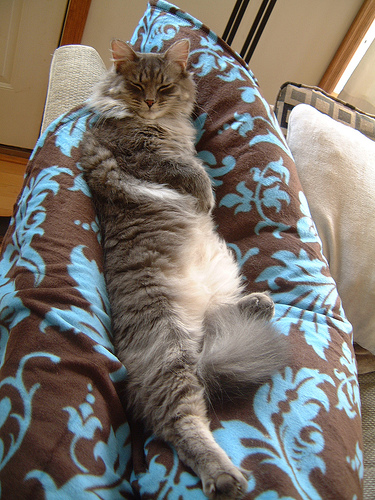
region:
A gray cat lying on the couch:
[68, 38, 264, 492]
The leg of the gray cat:
[152, 413, 243, 467]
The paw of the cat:
[197, 458, 257, 499]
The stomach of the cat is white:
[141, 188, 246, 318]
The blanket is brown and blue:
[224, 95, 348, 491]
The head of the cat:
[109, 34, 199, 124]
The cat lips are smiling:
[127, 104, 174, 118]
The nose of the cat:
[140, 96, 158, 109]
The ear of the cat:
[159, 35, 192, 75]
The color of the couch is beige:
[40, 35, 106, 152]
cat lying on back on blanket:
[83, 28, 277, 497]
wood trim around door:
[59, 4, 86, 54]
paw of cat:
[197, 465, 261, 495]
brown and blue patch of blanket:
[6, 306, 131, 495]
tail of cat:
[185, 300, 288, 420]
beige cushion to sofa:
[285, 103, 373, 295]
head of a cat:
[102, 29, 194, 120]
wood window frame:
[311, 3, 364, 99]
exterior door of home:
[2, 17, 48, 153]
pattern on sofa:
[276, 69, 369, 133]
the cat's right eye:
[129, 75, 146, 92]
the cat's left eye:
[156, 76, 173, 92]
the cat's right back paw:
[193, 445, 254, 498]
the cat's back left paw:
[228, 285, 277, 321]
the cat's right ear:
[109, 34, 141, 68]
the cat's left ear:
[160, 30, 195, 68]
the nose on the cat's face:
[143, 95, 156, 105]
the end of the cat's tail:
[201, 303, 286, 395]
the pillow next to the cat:
[277, 79, 373, 359]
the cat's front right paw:
[190, 162, 221, 216]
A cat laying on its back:
[87, 29, 270, 495]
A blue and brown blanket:
[16, 130, 125, 496]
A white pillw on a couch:
[292, 112, 371, 309]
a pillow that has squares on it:
[279, 75, 359, 123]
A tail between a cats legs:
[208, 309, 285, 394]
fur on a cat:
[101, 177, 199, 339]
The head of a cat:
[101, 30, 199, 132]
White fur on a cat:
[186, 235, 238, 323]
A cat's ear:
[160, 33, 207, 69]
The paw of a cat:
[177, 447, 264, 498]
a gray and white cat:
[64, 28, 304, 498]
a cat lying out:
[73, 29, 314, 498]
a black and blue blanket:
[5, 2, 371, 498]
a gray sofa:
[28, 37, 114, 164]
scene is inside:
[4, 3, 374, 498]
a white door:
[0, 0, 75, 169]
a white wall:
[83, 1, 350, 117]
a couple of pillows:
[260, 59, 373, 347]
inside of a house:
[3, 7, 367, 495]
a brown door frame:
[60, 2, 86, 54]